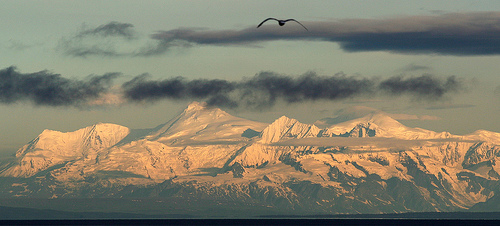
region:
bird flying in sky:
[246, 7, 313, 40]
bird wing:
[286, 14, 309, 31]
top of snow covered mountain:
[181, 93, 206, 116]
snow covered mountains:
[14, 98, 499, 213]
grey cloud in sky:
[70, 10, 138, 43]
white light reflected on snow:
[391, 121, 423, 143]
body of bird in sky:
[276, 21, 287, 28]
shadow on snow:
[186, 162, 229, 179]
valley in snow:
[103, 127, 155, 152]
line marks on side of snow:
[265, 130, 278, 145]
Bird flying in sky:
[255, 16, 307, 33]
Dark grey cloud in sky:
[156, 11, 498, 57]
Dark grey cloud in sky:
[0, 63, 124, 110]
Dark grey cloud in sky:
[121, 69, 481, 114]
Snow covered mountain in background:
[147, 98, 267, 143]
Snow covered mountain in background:
[13, 118, 130, 159]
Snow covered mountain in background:
[255, 113, 323, 144]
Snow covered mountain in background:
[320, 108, 439, 141]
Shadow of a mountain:
[237, 123, 263, 138]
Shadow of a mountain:
[75, 166, 155, 183]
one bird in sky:
[236, 1, 328, 41]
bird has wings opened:
[245, 4, 313, 41]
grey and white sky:
[22, 19, 261, 125]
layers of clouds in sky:
[98, 0, 448, 106]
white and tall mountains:
[60, 105, 497, 209]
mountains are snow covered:
[11, 122, 459, 198]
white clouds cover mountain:
[183, 112, 481, 209]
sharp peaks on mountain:
[179, 82, 299, 152]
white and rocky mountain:
[27, 89, 183, 200]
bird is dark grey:
[245, 12, 323, 43]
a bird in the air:
[201, 8, 353, 56]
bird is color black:
[243, 7, 313, 43]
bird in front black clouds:
[234, 5, 324, 51]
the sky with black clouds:
[1, 7, 498, 111]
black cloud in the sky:
[328, 8, 498, 58]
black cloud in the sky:
[9, 65, 451, 110]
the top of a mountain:
[171, 91, 233, 122]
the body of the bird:
[276, 17, 288, 27]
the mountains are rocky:
[0, 87, 490, 202]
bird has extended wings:
[251, 11, 312, 36]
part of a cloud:
[269, 71, 298, 109]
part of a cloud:
[340, 130, 380, 159]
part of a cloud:
[314, 75, 346, 91]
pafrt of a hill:
[343, 196, 362, 215]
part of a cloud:
[261, 83, 293, 112]